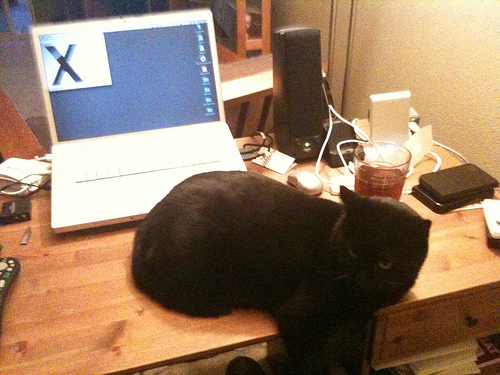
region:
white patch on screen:
[41, 36, 111, 93]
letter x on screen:
[43, 45, 85, 87]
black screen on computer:
[146, 80, 166, 102]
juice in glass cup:
[364, 175, 394, 194]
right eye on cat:
[372, 250, 399, 280]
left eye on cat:
[340, 240, 360, 267]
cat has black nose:
[352, 269, 369, 290]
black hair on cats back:
[223, 195, 258, 217]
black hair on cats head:
[370, 206, 392, 236]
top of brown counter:
[68, 296, 118, 336]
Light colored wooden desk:
[0, 113, 499, 373]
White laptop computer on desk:
[29, 8, 251, 235]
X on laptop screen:
[35, 29, 113, 92]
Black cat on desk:
[132, 168, 433, 373]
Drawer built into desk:
[371, 275, 499, 371]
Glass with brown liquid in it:
[352, 139, 412, 206]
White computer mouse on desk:
[286, 167, 325, 197]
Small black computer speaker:
[271, 24, 328, 161]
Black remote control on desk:
[0, 253, 21, 315]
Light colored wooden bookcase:
[147, 0, 272, 69]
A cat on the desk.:
[137, 181, 414, 350]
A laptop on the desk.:
[30, 32, 248, 194]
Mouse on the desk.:
[289, 137, 334, 194]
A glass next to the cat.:
[351, 130, 411, 216]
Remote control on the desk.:
[8, 244, 37, 321]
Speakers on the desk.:
[258, 4, 349, 171]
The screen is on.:
[51, 38, 212, 148]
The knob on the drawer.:
[453, 302, 484, 334]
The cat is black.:
[156, 214, 361, 314]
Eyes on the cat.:
[343, 239, 394, 272]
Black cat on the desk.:
[120, 176, 432, 352]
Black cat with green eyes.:
[316, 227, 414, 290]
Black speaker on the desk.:
[272, 13, 324, 169]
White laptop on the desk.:
[35, 3, 233, 235]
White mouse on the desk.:
[284, 150, 344, 195]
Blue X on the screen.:
[48, 29, 98, 102]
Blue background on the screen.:
[119, 30, 178, 126]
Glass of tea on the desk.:
[344, 136, 413, 196]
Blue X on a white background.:
[37, 23, 114, 105]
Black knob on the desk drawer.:
[456, 310, 483, 336]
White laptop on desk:
[29, 9, 254, 236]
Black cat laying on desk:
[130, 170, 431, 374]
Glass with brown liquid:
[352, 138, 412, 207]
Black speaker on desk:
[272, 22, 332, 165]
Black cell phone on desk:
[419, 163, 499, 204]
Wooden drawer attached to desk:
[373, 281, 499, 368]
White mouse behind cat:
[284, 166, 326, 198]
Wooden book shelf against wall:
[164, 0, 271, 70]